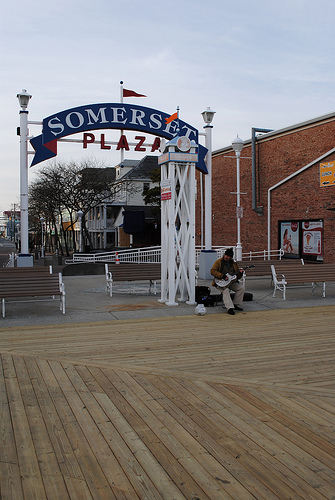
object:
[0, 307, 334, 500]
sidewalk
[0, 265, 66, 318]
bench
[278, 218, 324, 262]
poster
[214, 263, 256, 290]
guitar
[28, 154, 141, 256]
tree branches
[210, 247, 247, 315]
man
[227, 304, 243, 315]
shoes